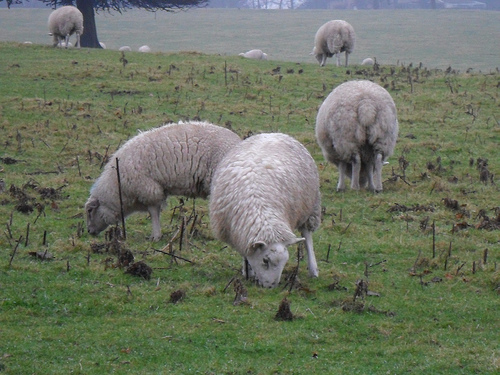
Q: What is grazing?
A: Herd.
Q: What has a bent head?
A: Sheep.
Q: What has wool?
A: Sheep.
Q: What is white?
A: Sheep.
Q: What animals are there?
A: Sheep.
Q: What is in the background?
A: More sheep.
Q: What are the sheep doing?
A: Grazing.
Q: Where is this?
A: Field.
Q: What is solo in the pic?
A: Tree.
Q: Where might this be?
A: Farm.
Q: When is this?
A: Afternoon.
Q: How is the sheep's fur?
A: Curly.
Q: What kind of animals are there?
A: Sheep.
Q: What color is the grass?
A: Green.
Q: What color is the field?
A: Green.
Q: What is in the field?
A: Grass and weeds.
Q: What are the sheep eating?
A: Grass.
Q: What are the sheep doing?
A: Eating.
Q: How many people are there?
A: None.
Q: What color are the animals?
A: White.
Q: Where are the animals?
A: In a grass area.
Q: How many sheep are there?
A: Five.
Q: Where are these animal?
A: In an outdoor scene.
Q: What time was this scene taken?
A: In day time.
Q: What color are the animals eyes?
A: Black.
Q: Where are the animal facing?
A: Down.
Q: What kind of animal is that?
A: Flock of sheeps.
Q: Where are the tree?
A: In the prairie.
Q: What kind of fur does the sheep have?
A: Wool.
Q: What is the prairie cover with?
A: Green grass.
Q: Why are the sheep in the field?
A: To graze.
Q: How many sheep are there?
A: Five.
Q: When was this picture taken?
A: During the day.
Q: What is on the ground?
A: Grass.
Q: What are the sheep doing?
A: Eating.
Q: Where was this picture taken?
A: In a field.